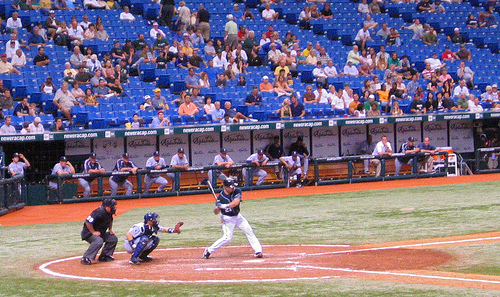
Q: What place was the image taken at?
A: It was taken at the field.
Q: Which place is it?
A: It is a field.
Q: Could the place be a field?
A: Yes, it is a field.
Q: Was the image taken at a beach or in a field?
A: It was taken at a field.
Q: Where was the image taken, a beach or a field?
A: It was taken at a field.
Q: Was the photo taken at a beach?
A: No, the picture was taken in a field.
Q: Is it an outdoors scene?
A: Yes, it is outdoors.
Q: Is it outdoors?
A: Yes, it is outdoors.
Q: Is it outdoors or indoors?
A: It is outdoors.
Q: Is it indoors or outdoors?
A: It is outdoors.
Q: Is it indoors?
A: No, it is outdoors.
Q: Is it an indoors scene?
A: No, it is outdoors.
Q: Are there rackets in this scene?
A: No, there are no rackets.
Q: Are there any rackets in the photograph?
A: No, there are no rackets.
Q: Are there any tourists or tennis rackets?
A: No, there are no tennis rackets or tourists.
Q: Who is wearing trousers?
A: The player is wearing trousers.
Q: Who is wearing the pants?
A: The player is wearing trousers.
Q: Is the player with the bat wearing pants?
A: Yes, the player is wearing pants.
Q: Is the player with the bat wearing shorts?
A: No, the player is wearing pants.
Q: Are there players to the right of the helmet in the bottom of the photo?
A: Yes, there is a player to the right of the helmet.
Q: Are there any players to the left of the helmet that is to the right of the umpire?
A: No, the player is to the right of the helmet.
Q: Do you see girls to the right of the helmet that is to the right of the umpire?
A: No, there is a player to the right of the helmet.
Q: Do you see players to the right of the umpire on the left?
A: Yes, there is a player to the right of the umpire.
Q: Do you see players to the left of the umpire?
A: No, the player is to the right of the umpire.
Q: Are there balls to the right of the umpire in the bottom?
A: No, there is a player to the right of the umpire.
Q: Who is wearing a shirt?
A: The player is wearing a shirt.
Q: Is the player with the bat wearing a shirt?
A: Yes, the player is wearing a shirt.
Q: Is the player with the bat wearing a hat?
A: No, the player is wearing a shirt.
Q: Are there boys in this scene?
A: No, there are no boys.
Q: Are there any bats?
A: Yes, there is a bat.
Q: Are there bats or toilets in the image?
A: Yes, there is a bat.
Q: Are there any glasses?
A: No, there are no glasses.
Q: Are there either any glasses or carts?
A: No, there are no glasses or carts.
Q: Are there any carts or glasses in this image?
A: No, there are no glasses or carts.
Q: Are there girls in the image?
A: No, there are no girls.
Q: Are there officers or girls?
A: No, there are no girls or officers.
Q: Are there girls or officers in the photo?
A: No, there are no girls or officers.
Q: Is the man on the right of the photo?
A: Yes, the man is on the right of the image.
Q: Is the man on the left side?
A: No, the man is on the right of the image.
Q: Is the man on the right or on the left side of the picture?
A: The man is on the right of the image.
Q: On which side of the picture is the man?
A: The man is on the right of the image.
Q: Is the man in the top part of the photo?
A: Yes, the man is in the top of the image.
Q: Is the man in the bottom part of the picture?
A: No, the man is in the top of the image.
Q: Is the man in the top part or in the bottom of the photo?
A: The man is in the top of the image.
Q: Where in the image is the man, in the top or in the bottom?
A: The man is in the top of the image.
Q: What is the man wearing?
A: The man is wearing a shirt.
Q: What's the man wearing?
A: The man is wearing a shirt.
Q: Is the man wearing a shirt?
A: Yes, the man is wearing a shirt.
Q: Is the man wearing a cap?
A: No, the man is wearing a shirt.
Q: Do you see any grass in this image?
A: Yes, there is grass.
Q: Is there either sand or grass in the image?
A: Yes, there is grass.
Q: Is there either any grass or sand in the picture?
A: Yes, there is grass.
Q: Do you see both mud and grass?
A: No, there is grass but no mud.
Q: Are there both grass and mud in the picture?
A: No, there is grass but no mud.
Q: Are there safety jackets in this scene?
A: No, there are no safety jackets.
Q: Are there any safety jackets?
A: No, there are no safety jackets.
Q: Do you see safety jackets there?
A: No, there are no safety jackets.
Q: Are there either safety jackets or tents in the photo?
A: No, there are no safety jackets or tents.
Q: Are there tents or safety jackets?
A: No, there are no safety jackets or tents.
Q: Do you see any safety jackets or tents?
A: No, there are no safety jackets or tents.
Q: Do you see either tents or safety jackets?
A: No, there are no safety jackets or tents.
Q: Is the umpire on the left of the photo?
A: Yes, the umpire is on the left of the image.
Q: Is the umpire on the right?
A: No, the umpire is on the left of the image.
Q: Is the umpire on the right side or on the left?
A: The umpire is on the left of the image.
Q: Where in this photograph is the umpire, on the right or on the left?
A: The umpire is on the left of the image.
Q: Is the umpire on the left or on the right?
A: The umpire is on the left of the image.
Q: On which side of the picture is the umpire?
A: The umpire is on the left of the image.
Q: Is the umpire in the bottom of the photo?
A: Yes, the umpire is in the bottom of the image.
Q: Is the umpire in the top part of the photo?
A: No, the umpire is in the bottom of the image.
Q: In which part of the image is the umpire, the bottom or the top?
A: The umpire is in the bottom of the image.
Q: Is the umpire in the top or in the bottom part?
A: The umpire is in the bottom of the image.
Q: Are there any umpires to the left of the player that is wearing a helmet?
A: Yes, there is an umpire to the left of the player.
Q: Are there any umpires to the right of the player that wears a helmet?
A: No, the umpire is to the left of the player.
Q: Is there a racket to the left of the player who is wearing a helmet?
A: No, there is an umpire to the left of the player.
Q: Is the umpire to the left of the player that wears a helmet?
A: Yes, the umpire is to the left of the player.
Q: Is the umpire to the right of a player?
A: No, the umpire is to the left of a player.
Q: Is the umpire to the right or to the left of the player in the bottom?
A: The umpire is to the left of the player.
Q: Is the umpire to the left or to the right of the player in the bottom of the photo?
A: The umpire is to the left of the player.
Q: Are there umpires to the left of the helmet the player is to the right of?
A: Yes, there is an umpire to the left of the helmet.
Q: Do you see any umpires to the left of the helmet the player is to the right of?
A: Yes, there is an umpire to the left of the helmet.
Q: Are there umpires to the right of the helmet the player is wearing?
A: No, the umpire is to the left of the helmet.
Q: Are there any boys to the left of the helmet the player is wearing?
A: No, there is an umpire to the left of the helmet.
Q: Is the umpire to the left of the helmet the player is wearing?
A: Yes, the umpire is to the left of the helmet.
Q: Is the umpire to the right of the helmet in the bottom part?
A: No, the umpire is to the left of the helmet.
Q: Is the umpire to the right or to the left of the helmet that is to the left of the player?
A: The umpire is to the left of the helmet.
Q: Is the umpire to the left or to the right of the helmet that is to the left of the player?
A: The umpire is to the left of the helmet.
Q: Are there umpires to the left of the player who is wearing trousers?
A: Yes, there is an umpire to the left of the player.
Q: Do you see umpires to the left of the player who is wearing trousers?
A: Yes, there is an umpire to the left of the player.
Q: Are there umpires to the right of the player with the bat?
A: No, the umpire is to the left of the player.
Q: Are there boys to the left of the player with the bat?
A: No, there is an umpire to the left of the player.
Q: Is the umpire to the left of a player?
A: Yes, the umpire is to the left of a player.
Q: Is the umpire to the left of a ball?
A: No, the umpire is to the left of a player.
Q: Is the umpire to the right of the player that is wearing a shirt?
A: No, the umpire is to the left of the player.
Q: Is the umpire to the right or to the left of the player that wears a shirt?
A: The umpire is to the left of the player.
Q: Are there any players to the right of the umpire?
A: Yes, there is a player to the right of the umpire.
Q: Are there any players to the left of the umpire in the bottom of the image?
A: No, the player is to the right of the umpire.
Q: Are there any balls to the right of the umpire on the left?
A: No, there is a player to the right of the umpire.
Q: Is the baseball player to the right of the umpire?
A: Yes, the player is to the right of the umpire.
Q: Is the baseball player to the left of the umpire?
A: No, the player is to the right of the umpire.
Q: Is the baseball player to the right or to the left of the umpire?
A: The player is to the right of the umpire.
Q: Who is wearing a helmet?
A: The player is wearing a helmet.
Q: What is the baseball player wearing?
A: The player is wearing a helmet.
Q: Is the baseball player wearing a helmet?
A: Yes, the player is wearing a helmet.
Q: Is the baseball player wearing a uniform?
A: No, the player is wearing a helmet.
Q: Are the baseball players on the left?
A: Yes, the baseball players are on the left of the image.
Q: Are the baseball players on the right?
A: No, the baseball players are on the left of the image.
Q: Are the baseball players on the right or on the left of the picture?
A: The baseball players are on the left of the image.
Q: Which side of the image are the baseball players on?
A: The baseball players are on the left of the image.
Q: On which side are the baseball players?
A: The baseball players are on the left of the image.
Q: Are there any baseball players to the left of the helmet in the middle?
A: Yes, there are baseball players to the left of the helmet.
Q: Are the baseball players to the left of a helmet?
A: Yes, the baseball players are to the left of a helmet.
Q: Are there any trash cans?
A: No, there are no trash cans.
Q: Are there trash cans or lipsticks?
A: No, there are no trash cans or lipsticks.